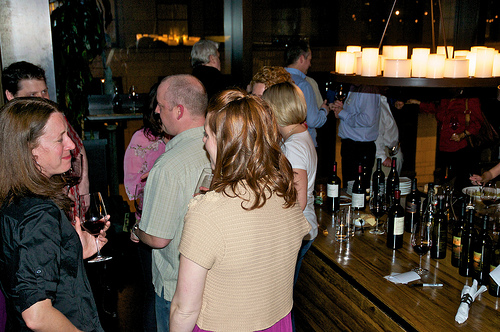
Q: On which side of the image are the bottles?
A: The bottles are on the right of the image.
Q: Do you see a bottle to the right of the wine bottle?
A: Yes, there are bottles to the right of the wine bottle.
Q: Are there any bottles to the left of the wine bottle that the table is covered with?
A: No, the bottles are to the right of the wine bottle.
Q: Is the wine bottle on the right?
A: Yes, the wine bottle is on the right of the image.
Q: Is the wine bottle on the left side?
A: No, the wine bottle is on the right of the image.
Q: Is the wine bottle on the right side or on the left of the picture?
A: The wine bottle is on the right of the image.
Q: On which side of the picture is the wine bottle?
A: The wine bottle is on the right of the image.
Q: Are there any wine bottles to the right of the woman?
A: Yes, there is a wine bottle to the right of the woman.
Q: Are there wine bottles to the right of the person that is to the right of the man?
A: Yes, there is a wine bottle to the right of the woman.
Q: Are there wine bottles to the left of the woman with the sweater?
A: No, the wine bottle is to the right of the woman.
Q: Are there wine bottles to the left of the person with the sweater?
A: No, the wine bottle is to the right of the woman.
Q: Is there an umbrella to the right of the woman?
A: No, there is a wine bottle to the right of the woman.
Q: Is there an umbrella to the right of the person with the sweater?
A: No, there is a wine bottle to the right of the woman.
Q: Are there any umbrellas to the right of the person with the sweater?
A: No, there is a wine bottle to the right of the woman.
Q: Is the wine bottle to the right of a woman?
A: Yes, the wine bottle is to the right of a woman.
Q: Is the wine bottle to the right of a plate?
A: No, the wine bottle is to the right of a woman.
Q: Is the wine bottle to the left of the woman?
A: No, the wine bottle is to the right of the woman.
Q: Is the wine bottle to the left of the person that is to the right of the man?
A: No, the wine bottle is to the right of the woman.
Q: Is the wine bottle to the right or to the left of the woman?
A: The wine bottle is to the right of the woman.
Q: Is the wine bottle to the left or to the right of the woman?
A: The wine bottle is to the right of the woman.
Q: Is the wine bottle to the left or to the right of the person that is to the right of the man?
A: The wine bottle is to the right of the woman.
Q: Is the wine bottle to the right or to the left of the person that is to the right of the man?
A: The wine bottle is to the right of the woman.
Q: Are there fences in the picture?
A: No, there are no fences.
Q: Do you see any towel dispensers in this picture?
A: No, there are no towel dispensers.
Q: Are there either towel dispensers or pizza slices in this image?
A: No, there are no towel dispensers or pizza slices.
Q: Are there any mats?
A: No, there are no mats.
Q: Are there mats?
A: No, there are no mats.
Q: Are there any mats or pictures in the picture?
A: No, there are no mats or pictures.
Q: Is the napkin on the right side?
A: Yes, the napkin is on the right of the image.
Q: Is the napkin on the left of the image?
A: No, the napkin is on the right of the image.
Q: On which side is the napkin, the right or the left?
A: The napkin is on the right of the image.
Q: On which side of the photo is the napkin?
A: The napkin is on the right of the image.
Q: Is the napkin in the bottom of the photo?
A: Yes, the napkin is in the bottom of the image.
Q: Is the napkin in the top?
A: No, the napkin is in the bottom of the image.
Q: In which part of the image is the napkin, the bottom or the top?
A: The napkin is in the bottom of the image.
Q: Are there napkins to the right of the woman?
A: Yes, there is a napkin to the right of the woman.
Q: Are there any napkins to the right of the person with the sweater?
A: Yes, there is a napkin to the right of the woman.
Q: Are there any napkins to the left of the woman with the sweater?
A: No, the napkin is to the right of the woman.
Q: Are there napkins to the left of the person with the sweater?
A: No, the napkin is to the right of the woman.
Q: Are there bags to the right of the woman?
A: No, there is a napkin to the right of the woman.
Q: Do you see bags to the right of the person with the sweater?
A: No, there is a napkin to the right of the woman.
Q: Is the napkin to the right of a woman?
A: Yes, the napkin is to the right of a woman.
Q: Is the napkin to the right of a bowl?
A: No, the napkin is to the right of a woman.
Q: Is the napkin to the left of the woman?
A: No, the napkin is to the right of the woman.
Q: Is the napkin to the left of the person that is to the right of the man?
A: No, the napkin is to the right of the woman.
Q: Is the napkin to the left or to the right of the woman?
A: The napkin is to the right of the woman.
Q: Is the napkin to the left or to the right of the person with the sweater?
A: The napkin is to the right of the woman.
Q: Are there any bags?
A: No, there are no bags.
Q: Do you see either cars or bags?
A: No, there are no bags or cars.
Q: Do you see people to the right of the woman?
A: Yes, there is a person to the right of the woman.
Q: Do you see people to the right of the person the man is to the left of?
A: Yes, there is a person to the right of the woman.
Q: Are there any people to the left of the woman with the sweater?
A: No, the person is to the right of the woman.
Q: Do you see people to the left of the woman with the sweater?
A: No, the person is to the right of the woman.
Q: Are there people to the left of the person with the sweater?
A: No, the person is to the right of the woman.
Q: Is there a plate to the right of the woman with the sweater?
A: No, there is a person to the right of the woman.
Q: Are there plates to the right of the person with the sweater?
A: No, there is a person to the right of the woman.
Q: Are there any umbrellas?
A: No, there are no umbrellas.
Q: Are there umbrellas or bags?
A: No, there are no umbrellas or bags.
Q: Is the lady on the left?
A: Yes, the lady is on the left of the image.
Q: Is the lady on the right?
A: No, the lady is on the left of the image.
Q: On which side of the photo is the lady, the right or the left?
A: The lady is on the left of the image.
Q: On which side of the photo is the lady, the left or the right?
A: The lady is on the left of the image.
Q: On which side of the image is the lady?
A: The lady is on the left of the image.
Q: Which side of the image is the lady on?
A: The lady is on the left of the image.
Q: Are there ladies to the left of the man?
A: Yes, there is a lady to the left of the man.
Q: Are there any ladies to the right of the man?
A: No, the lady is to the left of the man.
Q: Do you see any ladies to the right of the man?
A: No, the lady is to the left of the man.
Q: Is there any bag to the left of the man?
A: No, there is a lady to the left of the man.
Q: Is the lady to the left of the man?
A: Yes, the lady is to the left of the man.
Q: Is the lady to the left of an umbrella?
A: No, the lady is to the left of the man.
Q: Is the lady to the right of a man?
A: No, the lady is to the left of a man.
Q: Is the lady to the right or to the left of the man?
A: The lady is to the left of the man.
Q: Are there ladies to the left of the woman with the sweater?
A: Yes, there is a lady to the left of the woman.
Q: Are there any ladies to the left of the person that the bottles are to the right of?
A: Yes, there is a lady to the left of the woman.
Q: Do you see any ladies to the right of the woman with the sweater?
A: No, the lady is to the left of the woman.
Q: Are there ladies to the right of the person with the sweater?
A: No, the lady is to the left of the woman.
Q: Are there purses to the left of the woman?
A: No, there is a lady to the left of the woman.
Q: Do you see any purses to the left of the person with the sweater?
A: No, there is a lady to the left of the woman.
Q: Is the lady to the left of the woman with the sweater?
A: Yes, the lady is to the left of the woman.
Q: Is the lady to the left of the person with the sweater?
A: Yes, the lady is to the left of the woman.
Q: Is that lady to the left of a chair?
A: No, the lady is to the left of the woman.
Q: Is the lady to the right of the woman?
A: No, the lady is to the left of the woman.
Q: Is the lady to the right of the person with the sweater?
A: No, the lady is to the left of the woman.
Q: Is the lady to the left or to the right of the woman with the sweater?
A: The lady is to the left of the woman.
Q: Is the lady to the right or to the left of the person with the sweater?
A: The lady is to the left of the woman.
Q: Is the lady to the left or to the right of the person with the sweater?
A: The lady is to the left of the woman.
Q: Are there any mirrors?
A: No, there are no mirrors.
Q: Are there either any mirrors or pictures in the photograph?
A: No, there are no mirrors or pictures.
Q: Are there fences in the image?
A: No, there are no fences.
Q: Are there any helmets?
A: No, there are no helmets.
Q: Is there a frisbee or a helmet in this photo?
A: No, there are no helmets or frisbees.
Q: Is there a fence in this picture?
A: No, there are no fences.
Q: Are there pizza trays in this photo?
A: No, there are no pizza trays.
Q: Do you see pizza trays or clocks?
A: No, there are no pizza trays or clocks.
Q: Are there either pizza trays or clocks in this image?
A: No, there are no pizza trays or clocks.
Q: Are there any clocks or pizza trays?
A: No, there are no pizza trays or clocks.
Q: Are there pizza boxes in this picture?
A: No, there are no pizza boxes.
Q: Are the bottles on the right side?
A: Yes, the bottles are on the right of the image.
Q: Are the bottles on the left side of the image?
A: No, the bottles are on the right of the image.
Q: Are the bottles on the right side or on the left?
A: The bottles are on the right of the image.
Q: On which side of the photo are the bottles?
A: The bottles are on the right of the image.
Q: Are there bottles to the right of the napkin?
A: Yes, there are bottles to the right of the napkin.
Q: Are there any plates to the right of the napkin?
A: No, there are bottles to the right of the napkin.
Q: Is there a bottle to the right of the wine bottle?
A: Yes, there are bottles to the right of the wine bottle.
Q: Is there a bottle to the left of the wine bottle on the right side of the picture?
A: No, the bottles are to the right of the wine bottle.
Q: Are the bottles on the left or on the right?
A: The bottles are on the right of the image.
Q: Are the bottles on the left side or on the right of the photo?
A: The bottles are on the right of the image.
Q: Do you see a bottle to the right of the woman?
A: Yes, there are bottles to the right of the woman.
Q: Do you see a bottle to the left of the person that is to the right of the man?
A: No, the bottles are to the right of the woman.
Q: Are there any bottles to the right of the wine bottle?
A: Yes, there are bottles to the right of the wine bottle.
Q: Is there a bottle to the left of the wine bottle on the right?
A: No, the bottles are to the right of the wine bottle.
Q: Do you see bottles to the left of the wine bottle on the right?
A: No, the bottles are to the right of the wine bottle.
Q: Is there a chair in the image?
A: No, there are no chairs.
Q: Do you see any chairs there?
A: No, there are no chairs.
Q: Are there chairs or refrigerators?
A: No, there are no chairs or refrigerators.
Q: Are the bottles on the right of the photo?
A: Yes, the bottles are on the right of the image.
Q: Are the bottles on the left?
A: No, the bottles are on the right of the image.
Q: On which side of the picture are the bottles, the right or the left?
A: The bottles are on the right of the image.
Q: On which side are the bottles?
A: The bottles are on the right of the image.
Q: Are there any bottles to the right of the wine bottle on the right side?
A: Yes, there are bottles to the right of the wine bottle.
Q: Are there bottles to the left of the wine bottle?
A: No, the bottles are to the right of the wine bottle.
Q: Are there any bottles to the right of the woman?
A: Yes, there are bottles to the right of the woman.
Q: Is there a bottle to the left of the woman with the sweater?
A: No, the bottles are to the right of the woman.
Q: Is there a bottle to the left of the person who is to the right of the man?
A: No, the bottles are to the right of the woman.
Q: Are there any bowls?
A: No, there are no bowls.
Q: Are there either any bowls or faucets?
A: No, there are no bowls or faucets.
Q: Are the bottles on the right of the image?
A: Yes, the bottles are on the right of the image.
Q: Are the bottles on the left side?
A: No, the bottles are on the right of the image.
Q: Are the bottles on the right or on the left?
A: The bottles are on the right of the image.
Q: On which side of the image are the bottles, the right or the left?
A: The bottles are on the right of the image.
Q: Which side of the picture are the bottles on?
A: The bottles are on the right of the image.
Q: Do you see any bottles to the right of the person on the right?
A: No, the bottles are to the left of the person.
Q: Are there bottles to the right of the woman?
A: Yes, there are bottles to the right of the woman.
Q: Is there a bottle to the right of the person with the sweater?
A: Yes, there are bottles to the right of the woman.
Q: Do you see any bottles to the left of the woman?
A: No, the bottles are to the right of the woman.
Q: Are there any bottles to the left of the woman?
A: No, the bottles are to the right of the woman.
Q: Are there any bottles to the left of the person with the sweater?
A: No, the bottles are to the right of the woman.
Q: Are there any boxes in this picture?
A: No, there are no boxes.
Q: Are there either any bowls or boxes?
A: No, there are no boxes or bowls.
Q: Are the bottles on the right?
A: Yes, the bottles are on the right of the image.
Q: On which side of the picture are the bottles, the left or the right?
A: The bottles are on the right of the image.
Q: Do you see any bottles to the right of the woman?
A: Yes, there are bottles to the right of the woman.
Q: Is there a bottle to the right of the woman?
A: Yes, there are bottles to the right of the woman.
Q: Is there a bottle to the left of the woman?
A: No, the bottles are to the right of the woman.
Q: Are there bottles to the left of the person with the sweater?
A: No, the bottles are to the right of the woman.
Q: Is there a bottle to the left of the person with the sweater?
A: No, the bottles are to the right of the woman.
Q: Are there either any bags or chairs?
A: No, there are no bags or chairs.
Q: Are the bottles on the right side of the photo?
A: Yes, the bottles are on the right of the image.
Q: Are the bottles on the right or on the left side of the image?
A: The bottles are on the right of the image.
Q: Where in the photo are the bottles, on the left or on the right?
A: The bottles are on the right of the image.